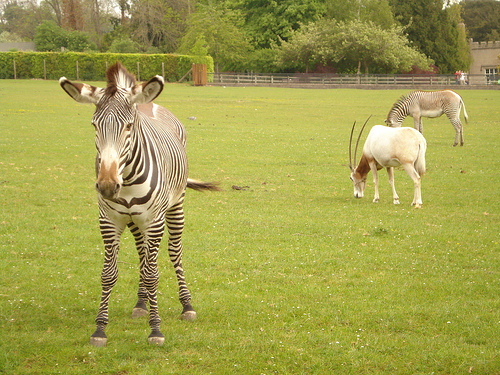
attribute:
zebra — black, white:
[54, 61, 225, 351]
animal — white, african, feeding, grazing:
[345, 113, 429, 211]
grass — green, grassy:
[0, 81, 499, 374]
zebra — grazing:
[386, 88, 471, 150]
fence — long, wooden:
[201, 72, 499, 88]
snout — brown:
[94, 174, 120, 197]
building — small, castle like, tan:
[467, 34, 499, 82]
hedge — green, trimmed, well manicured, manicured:
[0, 49, 215, 85]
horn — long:
[349, 116, 356, 174]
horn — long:
[354, 112, 375, 172]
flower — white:
[326, 339, 334, 347]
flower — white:
[270, 355, 276, 362]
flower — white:
[236, 324, 242, 332]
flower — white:
[197, 355, 203, 364]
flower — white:
[446, 318, 452, 326]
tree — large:
[173, 0, 252, 73]